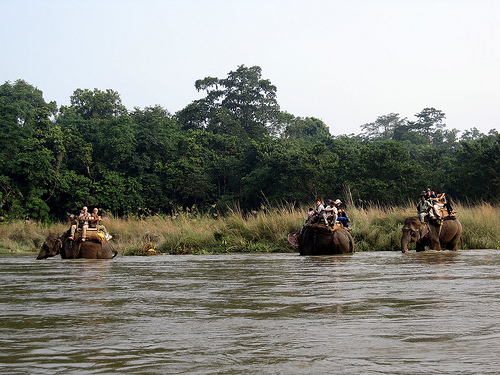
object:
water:
[0, 246, 500, 374]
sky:
[1, 0, 500, 126]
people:
[320, 198, 336, 228]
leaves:
[22, 123, 280, 190]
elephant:
[400, 213, 466, 254]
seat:
[430, 211, 459, 223]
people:
[436, 186, 453, 225]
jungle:
[0, 60, 500, 204]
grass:
[114, 217, 287, 245]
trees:
[353, 111, 425, 198]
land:
[4, 199, 497, 228]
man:
[79, 206, 90, 226]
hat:
[81, 206, 89, 213]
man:
[416, 194, 432, 225]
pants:
[421, 211, 429, 222]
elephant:
[35, 228, 117, 265]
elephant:
[287, 220, 355, 257]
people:
[64, 207, 93, 239]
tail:
[109, 247, 122, 263]